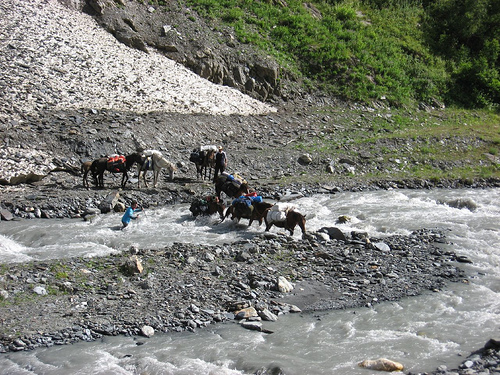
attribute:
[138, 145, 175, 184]
horse — white, crossing, carrying, fast, carries, six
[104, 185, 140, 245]
man — standing, stand, guiding, wearing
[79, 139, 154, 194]
horse — brown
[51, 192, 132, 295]
river — fast, water, flowing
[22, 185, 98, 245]
rock — large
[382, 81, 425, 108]
bush — growing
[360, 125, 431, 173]
pebble — small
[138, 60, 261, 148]
stone — covered, white, large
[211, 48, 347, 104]
hill — steep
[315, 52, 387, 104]
shrub — green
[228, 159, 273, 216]
top — blue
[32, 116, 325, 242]
donkeys — crossing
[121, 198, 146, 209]
hat — grown